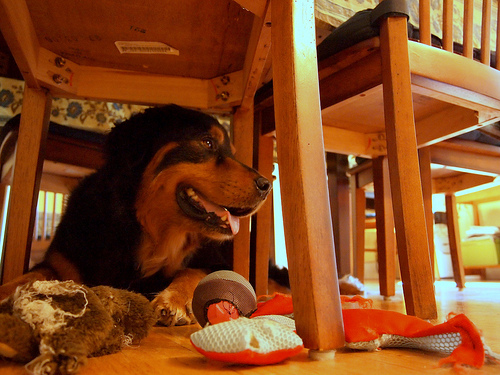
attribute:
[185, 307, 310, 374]
toy — red and white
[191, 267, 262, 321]
ball — Small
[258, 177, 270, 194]
snout — black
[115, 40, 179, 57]
label — attached 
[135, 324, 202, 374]
floor — Brown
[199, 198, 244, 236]
tongue — Red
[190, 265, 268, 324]
toy ball — small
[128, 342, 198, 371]
hardwood floor — Brown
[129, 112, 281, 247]
face — dog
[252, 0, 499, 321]
chair — Brown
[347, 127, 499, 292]
chair — Brown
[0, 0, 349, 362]
chair — Brown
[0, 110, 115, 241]
chair — Brown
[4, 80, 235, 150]
table cloth — White, Flowered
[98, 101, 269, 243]
head — black and brown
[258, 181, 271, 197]
nostril — small, black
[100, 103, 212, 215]
fur — black